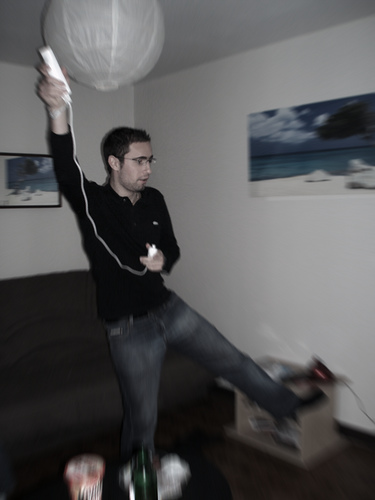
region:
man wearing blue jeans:
[106, 284, 288, 455]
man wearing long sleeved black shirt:
[40, 126, 191, 319]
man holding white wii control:
[37, 45, 165, 283]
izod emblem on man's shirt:
[152, 217, 160, 228]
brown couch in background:
[5, 246, 228, 475]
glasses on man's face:
[125, 149, 162, 167]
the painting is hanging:
[246, 92, 374, 197]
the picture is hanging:
[0, 151, 61, 207]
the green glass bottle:
[133, 440, 158, 498]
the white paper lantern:
[43, 0, 166, 90]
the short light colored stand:
[217, 353, 350, 469]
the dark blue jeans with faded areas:
[103, 289, 285, 452]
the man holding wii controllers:
[35, 46, 326, 457]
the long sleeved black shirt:
[47, 123, 179, 326]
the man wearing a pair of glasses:
[36, 62, 326, 457]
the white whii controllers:
[37, 44, 156, 275]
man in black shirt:
[36, 53, 304, 434]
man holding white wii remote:
[23, 42, 203, 351]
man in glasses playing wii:
[105, 133, 191, 198]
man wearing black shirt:
[45, 123, 201, 352]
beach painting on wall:
[235, 90, 361, 199]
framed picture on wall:
[2, 150, 80, 213]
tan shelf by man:
[217, 335, 347, 480]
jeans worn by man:
[79, 302, 292, 473]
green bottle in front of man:
[128, 444, 168, 489]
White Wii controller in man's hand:
[35, 44, 70, 104]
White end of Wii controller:
[141, 243, 156, 261]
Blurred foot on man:
[293, 386, 328, 422]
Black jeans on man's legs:
[111, 294, 295, 467]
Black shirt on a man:
[40, 129, 178, 312]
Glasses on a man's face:
[127, 155, 157, 166]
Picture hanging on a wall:
[246, 92, 372, 195]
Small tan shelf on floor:
[216, 354, 346, 466]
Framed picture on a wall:
[2, 150, 61, 210]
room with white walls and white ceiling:
[6, 7, 371, 438]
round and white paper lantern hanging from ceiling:
[32, 2, 172, 93]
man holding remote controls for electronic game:
[32, 43, 183, 317]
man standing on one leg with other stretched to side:
[82, 122, 330, 494]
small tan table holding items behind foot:
[220, 342, 347, 471]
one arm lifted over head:
[30, 43, 166, 199]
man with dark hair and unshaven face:
[97, 123, 157, 194]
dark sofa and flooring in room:
[7, 254, 371, 494]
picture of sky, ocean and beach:
[242, 92, 371, 198]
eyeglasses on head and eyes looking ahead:
[103, 122, 158, 190]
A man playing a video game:
[28, 39, 303, 461]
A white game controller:
[32, 39, 71, 102]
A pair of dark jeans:
[96, 287, 301, 456]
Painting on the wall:
[243, 86, 372, 201]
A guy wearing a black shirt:
[47, 124, 190, 332]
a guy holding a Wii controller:
[25, 39, 194, 287]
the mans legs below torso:
[99, 298, 298, 489]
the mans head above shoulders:
[102, 123, 153, 195]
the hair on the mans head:
[102, 118, 147, 158]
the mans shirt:
[52, 139, 184, 314]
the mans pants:
[103, 283, 278, 473]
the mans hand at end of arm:
[33, 82, 74, 123]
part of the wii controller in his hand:
[139, 241, 160, 274]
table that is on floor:
[233, 342, 342, 469]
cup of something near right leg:
[60, 443, 110, 496]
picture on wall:
[237, 95, 373, 203]